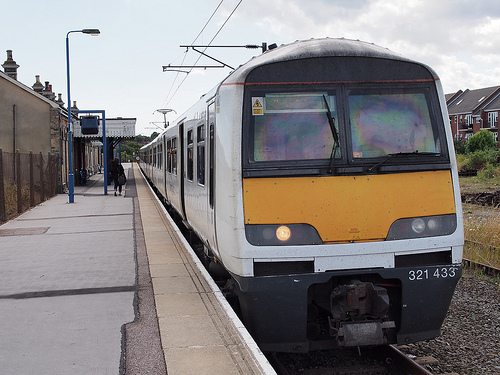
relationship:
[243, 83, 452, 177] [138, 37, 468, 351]
windshield on train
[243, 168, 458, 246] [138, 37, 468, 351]
panel on train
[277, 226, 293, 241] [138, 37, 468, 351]
light on train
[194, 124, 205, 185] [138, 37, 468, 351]
window on train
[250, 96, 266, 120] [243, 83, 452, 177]
sticker on windshield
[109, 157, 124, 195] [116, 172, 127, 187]
woman carrying bag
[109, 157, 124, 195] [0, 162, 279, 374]
woman on floor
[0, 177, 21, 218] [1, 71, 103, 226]
mural on wall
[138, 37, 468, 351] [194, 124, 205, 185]
train has window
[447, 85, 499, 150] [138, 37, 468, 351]
house by train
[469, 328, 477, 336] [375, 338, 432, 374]
gravel by rail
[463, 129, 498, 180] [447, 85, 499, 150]
tree by house